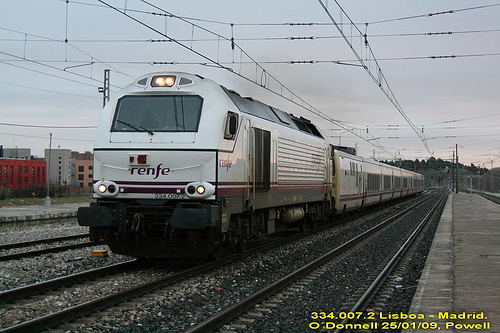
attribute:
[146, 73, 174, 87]
headlights — small, lit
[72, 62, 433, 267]
train — grey, large, white, silver, long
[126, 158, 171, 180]
label — burgandy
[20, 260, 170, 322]
tracks — steel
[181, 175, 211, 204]
headlights — on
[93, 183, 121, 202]
headlights — on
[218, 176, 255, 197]
stripes — burgandy, red, brown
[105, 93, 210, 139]
windsheild — large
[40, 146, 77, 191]
building — red, wide, large, grey, small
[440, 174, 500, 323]
walk — cement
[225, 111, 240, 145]
mirror — small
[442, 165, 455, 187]
light — red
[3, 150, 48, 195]
building — red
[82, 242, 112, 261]
object — orange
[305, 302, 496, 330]
watermark — yellow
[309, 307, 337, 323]
text — yellow